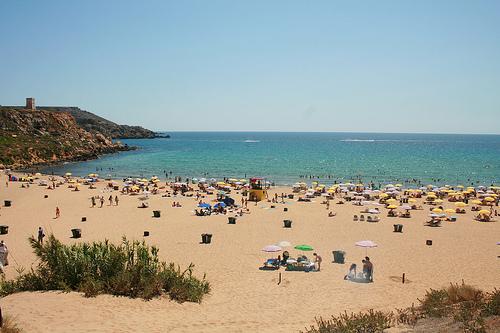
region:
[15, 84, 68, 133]
block building on hillside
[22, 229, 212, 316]
shrubs on beach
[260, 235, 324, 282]
people on beach under umbrella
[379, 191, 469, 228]
yellow beach umbrellas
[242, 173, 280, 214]
red and yellow lifeguard stand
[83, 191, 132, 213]
people walking on the beach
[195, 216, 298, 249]
black trash cans on the beach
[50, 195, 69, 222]
man in red shirt on the beach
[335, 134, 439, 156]
white caps of waves in the ocean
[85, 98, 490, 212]
clear blue ocean water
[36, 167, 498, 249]
a pretty crowded beach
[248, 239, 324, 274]
a remote group of umbrellas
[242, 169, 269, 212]
a lifeguard stand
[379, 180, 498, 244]
an area of predominately yellow umbrellas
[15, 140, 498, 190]
a calm ocean bay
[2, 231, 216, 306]
a bushy area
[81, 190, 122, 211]
people taking a walk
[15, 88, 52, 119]
a structure on a hill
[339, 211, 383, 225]
a group of chairs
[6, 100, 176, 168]
a rocky hillside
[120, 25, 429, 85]
Clear blue sky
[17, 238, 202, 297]
Bushes on a beach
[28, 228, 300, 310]
Green plants on sand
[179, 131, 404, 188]
Blue and green water by a beach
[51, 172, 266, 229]
Crowd of people on a bach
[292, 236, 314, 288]
Green umbrella on a beach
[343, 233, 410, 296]
White umbrella on a beach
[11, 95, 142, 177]
Plant covered cliff by a beach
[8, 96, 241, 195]
Cliffs by an ocean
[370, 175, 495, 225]
Several yellow beach umbrellas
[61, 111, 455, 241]
people on a beach near bright blue water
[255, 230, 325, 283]
small group of people on the sand with beach umbrellas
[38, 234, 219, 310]
green and brown bushes on the dunes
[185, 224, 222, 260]
trash cans on the beach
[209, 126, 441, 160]
white lines in water from vehicle in the distance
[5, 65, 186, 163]
high mountain overlooks water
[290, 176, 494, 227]
section of beach with many yellow beach umbrellas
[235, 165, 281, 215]
yellow lifeguard stand with red umbrella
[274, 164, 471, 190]
people are in the blue water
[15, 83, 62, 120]
tall square structure on top of mountain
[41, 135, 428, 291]
People relaxing on a beach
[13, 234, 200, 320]
Tall green weeds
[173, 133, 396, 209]
Beautiful blue water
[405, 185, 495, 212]
People sitting under yellow umbrellas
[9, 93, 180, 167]
Rocky landscape surrounded by water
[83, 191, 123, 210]
People walking on sand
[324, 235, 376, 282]
Group of people under a white umbrella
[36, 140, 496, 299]
People playing and relaxing on sand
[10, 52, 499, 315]
People enjoying sunny day on beach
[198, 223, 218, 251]
Garbage cans on beach